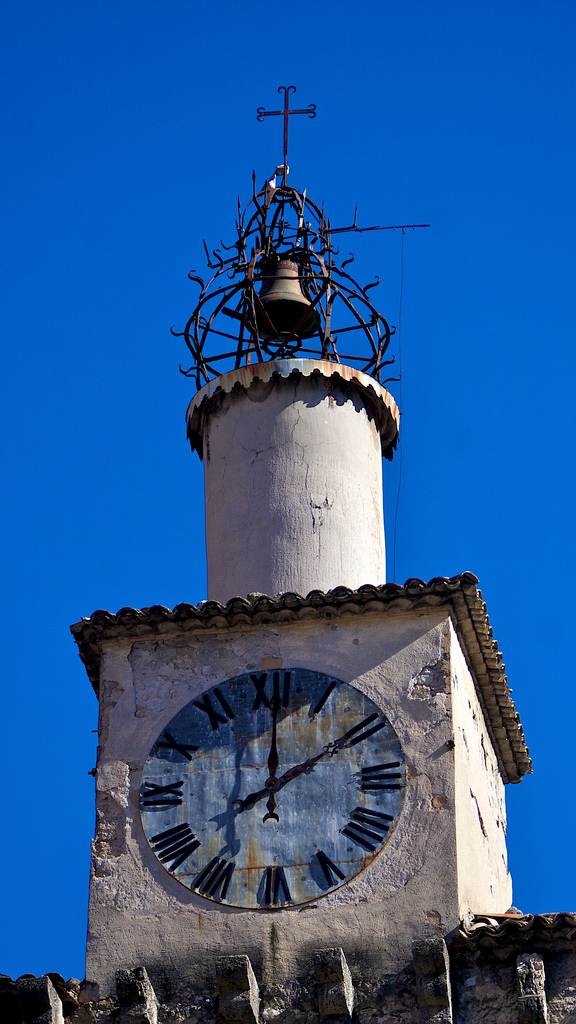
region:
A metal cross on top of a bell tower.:
[250, 82, 319, 159]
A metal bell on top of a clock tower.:
[256, 254, 315, 337]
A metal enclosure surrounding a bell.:
[168, 170, 392, 372]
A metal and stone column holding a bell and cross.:
[185, 357, 398, 601]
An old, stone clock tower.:
[93, 620, 455, 923]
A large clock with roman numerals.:
[142, 667, 407, 907]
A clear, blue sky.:
[322, 32, 572, 575]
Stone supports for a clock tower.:
[39, 942, 551, 1017]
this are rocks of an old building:
[131, 948, 341, 979]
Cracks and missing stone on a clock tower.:
[399, 650, 454, 714]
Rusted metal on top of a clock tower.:
[200, 352, 405, 412]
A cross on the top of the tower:
[247, 74, 340, 157]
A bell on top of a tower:
[243, 211, 342, 345]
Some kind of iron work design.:
[194, 192, 407, 371]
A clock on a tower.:
[116, 667, 434, 909]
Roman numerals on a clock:
[179, 678, 400, 906]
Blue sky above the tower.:
[30, 413, 155, 557]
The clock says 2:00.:
[116, 650, 436, 928]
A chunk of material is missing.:
[372, 624, 478, 748]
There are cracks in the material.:
[223, 394, 369, 579]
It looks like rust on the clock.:
[116, 674, 453, 925]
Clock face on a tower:
[132, 670, 402, 925]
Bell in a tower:
[196, 227, 378, 436]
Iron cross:
[236, 74, 333, 204]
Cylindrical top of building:
[175, 341, 447, 618]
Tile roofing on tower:
[425, 560, 569, 781]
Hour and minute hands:
[234, 672, 375, 846]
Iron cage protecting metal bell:
[187, 183, 414, 437]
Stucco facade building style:
[203, 405, 375, 607]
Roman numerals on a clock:
[240, 662, 347, 723]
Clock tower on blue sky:
[80, 92, 469, 1000]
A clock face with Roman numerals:
[140, 663, 410, 909]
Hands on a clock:
[216, 704, 355, 827]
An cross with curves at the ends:
[238, 67, 349, 205]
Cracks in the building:
[218, 398, 362, 489]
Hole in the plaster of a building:
[75, 754, 128, 902]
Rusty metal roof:
[176, 352, 422, 428]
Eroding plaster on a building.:
[92, 632, 458, 674]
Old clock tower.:
[44, 357, 504, 974]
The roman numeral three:
[350, 757, 410, 803]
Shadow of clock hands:
[210, 731, 260, 863]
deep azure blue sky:
[23, 13, 209, 222]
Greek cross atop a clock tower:
[253, 65, 331, 165]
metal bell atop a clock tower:
[246, 256, 319, 352]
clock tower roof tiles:
[441, 572, 543, 791]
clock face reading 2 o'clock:
[133, 649, 422, 914]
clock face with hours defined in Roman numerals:
[141, 672, 425, 907]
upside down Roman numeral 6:
[255, 855, 298, 915]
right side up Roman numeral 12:
[245, 673, 303, 717]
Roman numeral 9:
[134, 770, 192, 817]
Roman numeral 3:
[355, 755, 412, 794]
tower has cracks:
[183, 400, 410, 521]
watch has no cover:
[137, 757, 443, 910]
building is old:
[453, 734, 501, 940]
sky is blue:
[521, 809, 551, 860]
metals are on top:
[240, 61, 354, 186]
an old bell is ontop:
[261, 238, 363, 355]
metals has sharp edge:
[246, 155, 281, 217]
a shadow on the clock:
[206, 700, 276, 849]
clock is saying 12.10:
[246, 670, 389, 858]